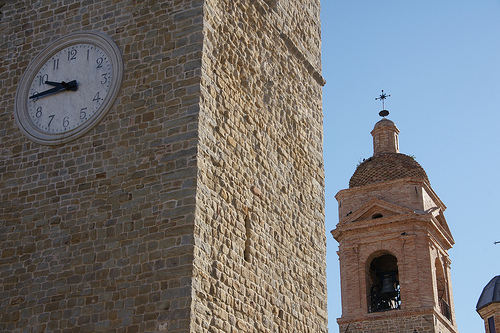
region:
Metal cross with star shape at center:
[372, 84, 394, 113]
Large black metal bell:
[369, 259, 401, 306]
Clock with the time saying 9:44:
[13, 27, 123, 148]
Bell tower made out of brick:
[330, 87, 458, 332]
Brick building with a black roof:
[466, 267, 498, 332]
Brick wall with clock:
[5, 2, 321, 332]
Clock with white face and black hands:
[9, 27, 125, 147]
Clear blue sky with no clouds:
[321, 3, 498, 332]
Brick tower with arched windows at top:
[330, 88, 456, 331]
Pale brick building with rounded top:
[330, 84, 456, 331]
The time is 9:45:
[9, 31, 146, 152]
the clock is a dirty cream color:
[6, 31, 153, 154]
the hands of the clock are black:
[11, 19, 121, 157]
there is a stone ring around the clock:
[4, 22, 141, 149]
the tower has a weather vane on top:
[372, 81, 410, 136]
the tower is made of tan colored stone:
[330, 168, 430, 330]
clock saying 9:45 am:
[12, 28, 122, 145]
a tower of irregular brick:
[1, 3, 327, 332]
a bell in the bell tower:
[377, 273, 399, 298]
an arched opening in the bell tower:
[363, 247, 400, 312]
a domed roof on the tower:
[345, 150, 429, 185]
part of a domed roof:
[475, 275, 497, 309]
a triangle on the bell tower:
[350, 203, 405, 226]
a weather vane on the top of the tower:
[373, 88, 393, 110]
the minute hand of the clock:
[24, 78, 77, 101]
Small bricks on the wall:
[101, 260, 177, 298]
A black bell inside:
[366, 263, 403, 296]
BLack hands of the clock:
[27, 73, 86, 105]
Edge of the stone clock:
[108, 39, 135, 72]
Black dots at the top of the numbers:
[50, 40, 110, 60]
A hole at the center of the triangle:
[329, 197, 422, 232]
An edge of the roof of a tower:
[473, 274, 498, 328]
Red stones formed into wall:
[400, 196, 436, 231]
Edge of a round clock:
[16, 117, 57, 149]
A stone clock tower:
[0, 3, 327, 332]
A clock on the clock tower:
[10, 31, 122, 146]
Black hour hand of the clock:
[41, 78, 76, 89]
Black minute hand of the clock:
[27, 80, 77, 100]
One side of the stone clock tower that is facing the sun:
[193, 0, 324, 331]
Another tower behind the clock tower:
[331, 117, 454, 332]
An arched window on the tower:
[362, 246, 398, 313]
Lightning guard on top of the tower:
[374, 87, 390, 119]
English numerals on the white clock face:
[33, 45, 105, 126]